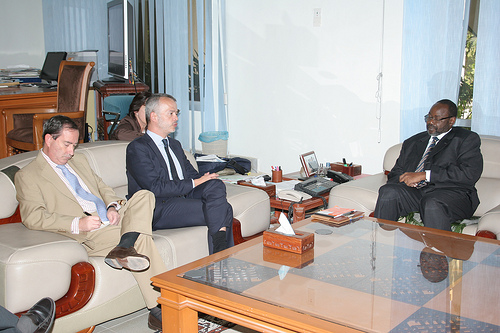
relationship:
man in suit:
[379, 99, 485, 236] [373, 127, 483, 240]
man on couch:
[126, 92, 241, 252] [0, 136, 275, 330]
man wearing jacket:
[16, 113, 177, 330] [12, 148, 126, 246]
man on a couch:
[126, 92, 241, 252] [0, 136, 275, 330]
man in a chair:
[379, 99, 485, 236] [329, 134, 500, 239]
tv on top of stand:
[100, 1, 140, 78] [92, 77, 147, 143]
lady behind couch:
[109, 94, 154, 146] [0, 136, 275, 330]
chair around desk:
[1, 57, 98, 163] [0, 68, 87, 152]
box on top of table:
[263, 211, 316, 254] [150, 210, 499, 332]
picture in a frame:
[303, 154, 317, 173] [297, 149, 323, 176]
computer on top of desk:
[35, 51, 71, 90] [0, 68, 87, 152]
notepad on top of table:
[314, 206, 356, 219] [150, 210, 499, 332]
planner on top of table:
[309, 213, 365, 224] [150, 210, 499, 332]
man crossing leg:
[126, 92, 241, 252] [179, 178, 230, 251]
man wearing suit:
[126, 92, 241, 252] [124, 132, 236, 255]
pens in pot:
[272, 165, 284, 173] [271, 168, 283, 182]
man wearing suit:
[379, 99, 485, 236] [373, 127, 483, 240]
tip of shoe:
[35, 296, 57, 310] [21, 294, 58, 332]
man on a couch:
[16, 113, 177, 330] [0, 136, 275, 330]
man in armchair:
[379, 99, 485, 236] [329, 134, 500, 239]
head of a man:
[40, 112, 86, 166] [16, 113, 177, 330]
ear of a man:
[147, 110, 157, 122] [126, 92, 241, 252]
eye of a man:
[168, 111, 174, 117] [126, 92, 241, 252]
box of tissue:
[263, 211, 316, 254] [275, 211, 292, 233]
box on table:
[263, 211, 316, 254] [150, 210, 499, 332]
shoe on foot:
[104, 243, 155, 273] [107, 238, 165, 281]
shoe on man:
[104, 243, 155, 273] [20, 103, 191, 307]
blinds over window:
[143, 0, 228, 152] [132, 6, 221, 163]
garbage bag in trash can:
[192, 122, 231, 144] [194, 131, 230, 163]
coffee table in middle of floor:
[149, 200, 498, 330] [70, 264, 260, 329]